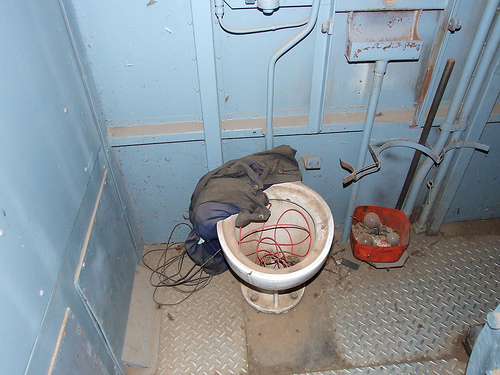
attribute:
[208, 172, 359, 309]
toilet — grey, dirty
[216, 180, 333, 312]
bucket — white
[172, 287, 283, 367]
floor — metal, dirty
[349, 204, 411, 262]
container — Orange 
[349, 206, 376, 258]
bucket — dirty, red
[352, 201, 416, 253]
bucket — red